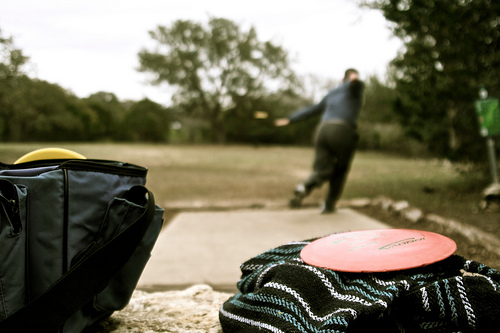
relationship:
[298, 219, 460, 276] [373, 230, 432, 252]
frisbee has lettering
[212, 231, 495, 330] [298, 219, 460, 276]
pullover with frisbee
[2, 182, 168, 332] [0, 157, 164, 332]
strap on bag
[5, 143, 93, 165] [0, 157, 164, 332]
frisbee in bag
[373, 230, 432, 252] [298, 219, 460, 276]
lettering on frisbee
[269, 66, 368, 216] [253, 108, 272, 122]
man throwing frisbee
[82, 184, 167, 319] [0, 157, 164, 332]
pocket in front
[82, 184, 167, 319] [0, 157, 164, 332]
pocket on front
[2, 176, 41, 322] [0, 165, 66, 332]
pocket on back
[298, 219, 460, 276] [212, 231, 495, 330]
frisbee on shirt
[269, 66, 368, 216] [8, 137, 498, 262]
person in field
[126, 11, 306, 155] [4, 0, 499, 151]
tree in background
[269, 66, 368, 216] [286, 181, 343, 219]
person has feet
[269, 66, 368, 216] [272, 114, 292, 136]
person has hand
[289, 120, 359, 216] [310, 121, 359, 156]
trouser has part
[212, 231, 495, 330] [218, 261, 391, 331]
sweater has hood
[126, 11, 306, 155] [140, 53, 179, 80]
tree has leaves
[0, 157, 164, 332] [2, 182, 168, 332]
bag has handle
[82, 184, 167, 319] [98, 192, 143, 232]
pocket has part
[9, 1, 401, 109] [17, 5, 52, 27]
clouds has part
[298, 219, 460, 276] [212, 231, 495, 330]
re disk on shirt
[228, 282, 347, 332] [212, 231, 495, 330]
stripes on hoodie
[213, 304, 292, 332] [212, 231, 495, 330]
stripe on hoodie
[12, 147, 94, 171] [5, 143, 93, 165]
edge on circle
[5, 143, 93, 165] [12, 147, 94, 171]
circle has edge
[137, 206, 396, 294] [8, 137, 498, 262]
slab on ground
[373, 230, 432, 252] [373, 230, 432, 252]
lettering on disk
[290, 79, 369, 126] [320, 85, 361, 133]
shirt covering torso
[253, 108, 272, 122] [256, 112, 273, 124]
disk being thrown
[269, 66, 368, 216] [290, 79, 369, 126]
man has shirt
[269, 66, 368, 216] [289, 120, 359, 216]
man has pants